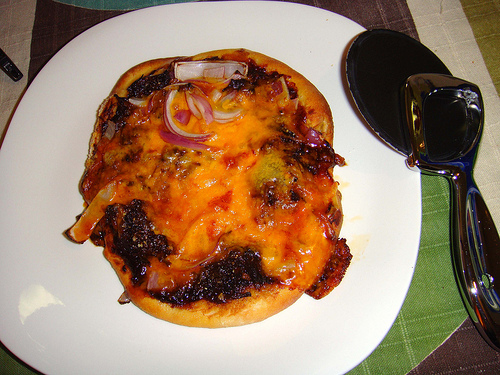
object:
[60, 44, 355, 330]
pizza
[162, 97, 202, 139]
onion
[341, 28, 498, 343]
spoon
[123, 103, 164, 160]
sauce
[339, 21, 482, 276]
spoon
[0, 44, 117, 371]
plate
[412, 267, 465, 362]
placemat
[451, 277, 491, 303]
light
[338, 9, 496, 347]
utensil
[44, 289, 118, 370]
plate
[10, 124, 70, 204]
plate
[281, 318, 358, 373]
plate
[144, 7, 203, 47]
plate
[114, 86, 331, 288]
cheese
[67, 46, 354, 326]
food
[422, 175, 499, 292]
pattern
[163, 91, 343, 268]
cheese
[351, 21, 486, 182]
spoon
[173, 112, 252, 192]
pizza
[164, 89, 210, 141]
onion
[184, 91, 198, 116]
onion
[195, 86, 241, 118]
onion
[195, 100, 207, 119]
onion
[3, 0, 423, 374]
plate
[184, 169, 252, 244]
cheese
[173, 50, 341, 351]
pizza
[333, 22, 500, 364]
pizza cutter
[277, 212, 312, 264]
sauce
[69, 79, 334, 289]
sauce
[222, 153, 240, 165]
sauce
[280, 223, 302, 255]
sauce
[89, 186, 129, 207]
sauce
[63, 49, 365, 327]
bread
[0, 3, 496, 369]
table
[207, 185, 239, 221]
sauce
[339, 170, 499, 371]
placemat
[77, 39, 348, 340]
pizza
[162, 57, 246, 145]
onions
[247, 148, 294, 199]
spot